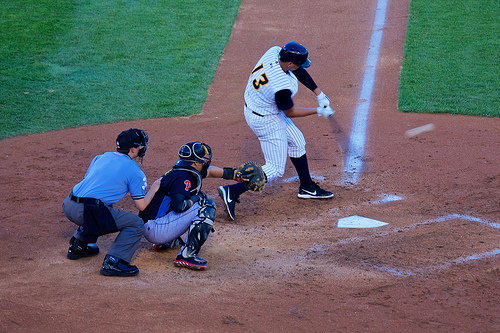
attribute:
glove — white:
[317, 94, 331, 108]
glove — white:
[317, 109, 333, 116]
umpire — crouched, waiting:
[60, 130, 153, 277]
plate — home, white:
[337, 211, 381, 232]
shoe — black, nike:
[298, 183, 332, 202]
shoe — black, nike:
[219, 181, 236, 218]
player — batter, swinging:
[235, 32, 323, 203]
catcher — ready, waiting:
[144, 141, 217, 266]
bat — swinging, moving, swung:
[324, 107, 364, 171]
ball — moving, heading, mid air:
[407, 118, 433, 139]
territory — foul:
[11, 7, 340, 158]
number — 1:
[252, 63, 266, 73]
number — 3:
[253, 72, 270, 90]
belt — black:
[243, 102, 263, 120]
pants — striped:
[240, 105, 300, 174]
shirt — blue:
[72, 156, 146, 205]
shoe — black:
[99, 258, 137, 275]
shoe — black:
[65, 237, 99, 258]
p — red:
[183, 179, 193, 192]